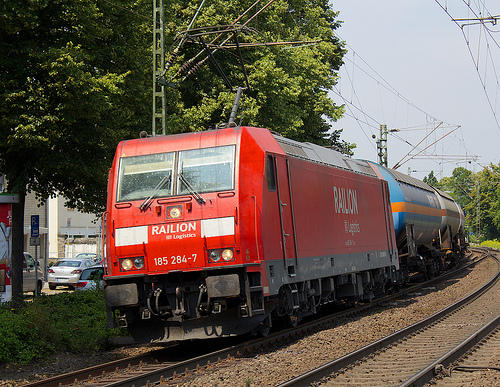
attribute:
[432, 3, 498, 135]
line — overhead, power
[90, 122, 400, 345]
train engine — red 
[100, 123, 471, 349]
train — blue 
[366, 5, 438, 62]
sky — blue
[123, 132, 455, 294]
engine — red 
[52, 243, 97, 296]
car — parked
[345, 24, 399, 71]
clouds — white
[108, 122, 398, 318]
train engine — red passenger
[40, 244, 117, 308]
car — parked, silver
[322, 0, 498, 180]
sky — blue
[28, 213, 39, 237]
sign — blue 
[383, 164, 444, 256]
tank car — blue orange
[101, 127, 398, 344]
train — red 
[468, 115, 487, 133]
white clouds — white 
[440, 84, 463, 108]
white clouds — white 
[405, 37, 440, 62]
white clouds — white 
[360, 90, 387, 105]
white clouds — white 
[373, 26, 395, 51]
white clouds — white 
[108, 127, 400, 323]
engine — red 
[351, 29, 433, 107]
sky — blue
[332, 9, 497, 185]
sky — overcast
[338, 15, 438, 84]
sky — blue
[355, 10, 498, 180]
clouds — white 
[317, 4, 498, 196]
sky — blue 